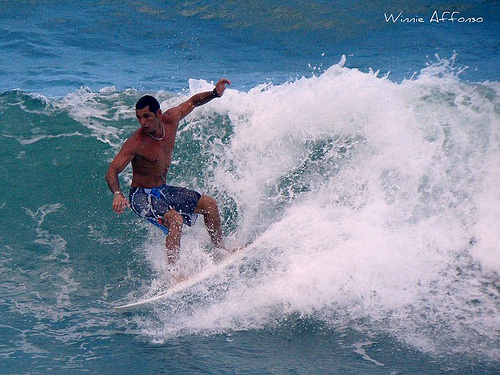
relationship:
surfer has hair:
[105, 78, 231, 265] [136, 92, 158, 112]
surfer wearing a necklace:
[105, 74, 228, 281] [138, 120, 167, 142]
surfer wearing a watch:
[105, 78, 231, 265] [109, 189, 124, 198]